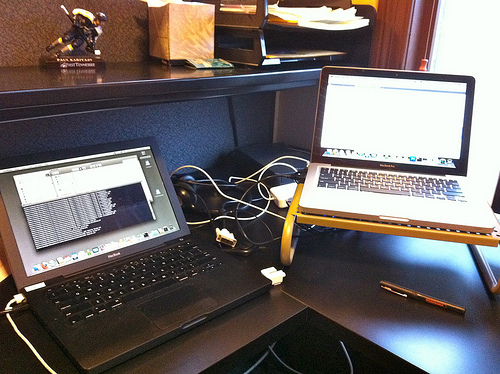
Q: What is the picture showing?
A: It is showing a station.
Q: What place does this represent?
A: It represents the station.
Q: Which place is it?
A: It is a station.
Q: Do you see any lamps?
A: No, there are no lamps.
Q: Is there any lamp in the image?
A: No, there are no lamps.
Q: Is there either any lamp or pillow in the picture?
A: No, there are no lamps or pillows.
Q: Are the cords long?
A: Yes, the cords are long.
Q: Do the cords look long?
A: Yes, the cords are long.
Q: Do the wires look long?
A: Yes, the wires are long.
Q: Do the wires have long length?
A: Yes, the wires are long.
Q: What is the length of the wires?
A: The wires are long.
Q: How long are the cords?
A: The cords are long.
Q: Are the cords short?
A: No, the cords are long.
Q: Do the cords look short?
A: No, the cords are long.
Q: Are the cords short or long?
A: The cords are long.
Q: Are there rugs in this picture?
A: No, there are no rugs.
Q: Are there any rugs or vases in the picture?
A: No, there are no rugs or vases.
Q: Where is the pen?
A: The pen is on the station.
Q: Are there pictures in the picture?
A: No, there are no pictures.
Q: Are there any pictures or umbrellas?
A: No, there are no pictures or umbrellas.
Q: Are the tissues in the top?
A: Yes, the tissues are in the top of the image.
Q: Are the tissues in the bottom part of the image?
A: No, the tissues are in the top of the image.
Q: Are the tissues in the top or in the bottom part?
A: The tissues are in the top of the image.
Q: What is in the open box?
A: The tissues are in the box.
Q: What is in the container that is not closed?
A: The tissues are in the box.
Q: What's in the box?
A: The tissues are in the box.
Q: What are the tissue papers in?
A: The tissue papers are in the box.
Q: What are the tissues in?
A: The tissue papers are in the box.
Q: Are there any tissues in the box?
A: Yes, there are tissues in the box.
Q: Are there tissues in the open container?
A: Yes, there are tissues in the box.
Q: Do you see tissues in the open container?
A: Yes, there are tissues in the box.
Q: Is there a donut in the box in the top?
A: No, there are tissues in the box.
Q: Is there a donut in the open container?
A: No, there are tissues in the box.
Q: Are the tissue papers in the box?
A: Yes, the tissue papers are in the box.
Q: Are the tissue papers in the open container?
A: Yes, the tissue papers are in the box.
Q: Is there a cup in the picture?
A: No, there are no cups.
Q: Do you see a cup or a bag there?
A: No, there are no cups or bags.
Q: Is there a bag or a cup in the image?
A: No, there are no cups or bags.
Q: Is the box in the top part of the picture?
A: Yes, the box is in the top of the image.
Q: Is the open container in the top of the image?
A: Yes, the box is in the top of the image.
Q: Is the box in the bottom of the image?
A: No, the box is in the top of the image.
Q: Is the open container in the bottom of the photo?
A: No, the box is in the top of the image.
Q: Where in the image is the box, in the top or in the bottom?
A: The box is in the top of the image.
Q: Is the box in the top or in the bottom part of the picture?
A: The box is in the top of the image.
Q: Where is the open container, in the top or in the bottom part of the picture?
A: The box is in the top of the image.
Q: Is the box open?
A: Yes, the box is open.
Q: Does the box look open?
A: Yes, the box is open.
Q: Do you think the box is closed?
A: No, the box is open.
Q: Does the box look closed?
A: No, the box is open.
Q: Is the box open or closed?
A: The box is open.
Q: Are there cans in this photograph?
A: No, there are no cans.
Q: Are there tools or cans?
A: No, there are no cans or tools.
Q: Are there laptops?
A: Yes, there is a laptop.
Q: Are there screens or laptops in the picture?
A: Yes, there is a laptop.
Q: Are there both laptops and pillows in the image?
A: No, there is a laptop but no pillows.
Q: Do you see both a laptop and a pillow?
A: No, there is a laptop but no pillows.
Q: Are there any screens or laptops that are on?
A: Yes, the laptop is on.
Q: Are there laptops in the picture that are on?
A: Yes, there is a laptop that is on.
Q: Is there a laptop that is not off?
A: Yes, there is a laptop that is on.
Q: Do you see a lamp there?
A: No, there are no lamps.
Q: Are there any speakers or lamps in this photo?
A: No, there are no lamps or speakers.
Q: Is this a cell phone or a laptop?
A: This is a laptop.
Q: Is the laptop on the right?
A: Yes, the laptop is on the right of the image.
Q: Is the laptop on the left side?
A: No, the laptop is on the right of the image.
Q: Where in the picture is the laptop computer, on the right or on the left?
A: The laptop computer is on the right of the image.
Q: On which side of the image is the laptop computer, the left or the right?
A: The laptop computer is on the right of the image.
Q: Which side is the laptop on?
A: The laptop is on the right of the image.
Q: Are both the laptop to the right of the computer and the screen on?
A: Yes, both the laptop and the screen are on.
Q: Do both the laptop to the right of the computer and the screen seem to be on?
A: Yes, both the laptop and the screen are on.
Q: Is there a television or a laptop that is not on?
A: No, there is a laptop but it is on.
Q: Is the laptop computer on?
A: Yes, the laptop computer is on.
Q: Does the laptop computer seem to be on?
A: Yes, the laptop computer is on.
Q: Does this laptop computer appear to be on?
A: Yes, the laptop computer is on.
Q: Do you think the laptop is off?
A: No, the laptop is on.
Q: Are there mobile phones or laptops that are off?
A: No, there is a laptop but it is on.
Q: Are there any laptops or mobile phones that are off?
A: No, there is a laptop but it is on.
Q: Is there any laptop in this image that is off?
A: No, there is a laptop but it is on.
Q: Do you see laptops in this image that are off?
A: No, there is a laptop but it is on.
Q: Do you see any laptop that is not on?
A: No, there is a laptop but it is on.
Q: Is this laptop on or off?
A: The laptop is on.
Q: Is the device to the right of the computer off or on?
A: The laptop is on.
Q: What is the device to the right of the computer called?
A: The device is a laptop.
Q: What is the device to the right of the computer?
A: The device is a laptop.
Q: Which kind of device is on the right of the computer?
A: The device is a laptop.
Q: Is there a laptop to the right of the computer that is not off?
A: Yes, there is a laptop to the right of the computer.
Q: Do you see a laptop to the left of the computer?
A: No, the laptop is to the right of the computer.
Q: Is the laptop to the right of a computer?
A: Yes, the laptop is to the right of a computer.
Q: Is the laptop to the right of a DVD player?
A: No, the laptop is to the right of a computer.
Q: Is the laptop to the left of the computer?
A: No, the laptop is to the right of the computer.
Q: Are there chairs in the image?
A: No, there are no chairs.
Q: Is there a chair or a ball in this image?
A: No, there are no chairs or balls.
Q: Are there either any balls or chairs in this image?
A: No, there are no chairs or balls.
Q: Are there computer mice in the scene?
A: Yes, there is a computer mouse.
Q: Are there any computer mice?
A: Yes, there is a computer mouse.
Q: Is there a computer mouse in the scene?
A: Yes, there is a computer mouse.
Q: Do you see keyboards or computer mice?
A: Yes, there is a computer mouse.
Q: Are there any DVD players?
A: No, there are no DVD players.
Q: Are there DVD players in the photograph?
A: No, there are no DVD players.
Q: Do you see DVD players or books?
A: No, there are no DVD players or books.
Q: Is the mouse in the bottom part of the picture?
A: Yes, the mouse is in the bottom of the image.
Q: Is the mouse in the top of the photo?
A: No, the mouse is in the bottom of the image.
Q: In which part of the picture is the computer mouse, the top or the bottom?
A: The computer mouse is in the bottom of the image.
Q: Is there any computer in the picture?
A: Yes, there is a computer.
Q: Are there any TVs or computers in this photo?
A: Yes, there is a computer.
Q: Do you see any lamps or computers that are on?
A: Yes, the computer is on.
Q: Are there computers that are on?
A: Yes, there is a computer that is on.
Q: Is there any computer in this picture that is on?
A: Yes, there is a computer that is on.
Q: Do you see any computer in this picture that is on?
A: Yes, there is a computer that is on.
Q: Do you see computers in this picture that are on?
A: Yes, there is a computer that is on.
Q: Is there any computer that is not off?
A: Yes, there is a computer that is on.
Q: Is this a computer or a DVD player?
A: This is a computer.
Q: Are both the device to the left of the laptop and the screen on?
A: Yes, both the computer and the screen are on.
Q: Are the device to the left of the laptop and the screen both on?
A: Yes, both the computer and the screen are on.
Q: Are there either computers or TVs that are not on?
A: No, there is a computer but it is on.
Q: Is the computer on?
A: Yes, the computer is on.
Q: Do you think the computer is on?
A: Yes, the computer is on.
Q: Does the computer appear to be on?
A: Yes, the computer is on.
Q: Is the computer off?
A: No, the computer is on.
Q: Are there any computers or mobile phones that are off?
A: No, there is a computer but it is on.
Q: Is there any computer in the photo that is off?
A: No, there is a computer but it is on.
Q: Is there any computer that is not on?
A: No, there is a computer but it is on.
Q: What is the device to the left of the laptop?
A: The device is a computer.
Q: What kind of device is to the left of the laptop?
A: The device is a computer.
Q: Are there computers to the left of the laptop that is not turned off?
A: Yes, there is a computer to the left of the laptop.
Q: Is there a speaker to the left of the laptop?
A: No, there is a computer to the left of the laptop.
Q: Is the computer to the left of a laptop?
A: Yes, the computer is to the left of a laptop.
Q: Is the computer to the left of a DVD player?
A: No, the computer is to the left of a laptop.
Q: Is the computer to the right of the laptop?
A: No, the computer is to the left of the laptop.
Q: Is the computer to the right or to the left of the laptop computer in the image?
A: The computer is to the left of the laptop computer.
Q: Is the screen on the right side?
A: Yes, the screen is on the right of the image.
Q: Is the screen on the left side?
A: No, the screen is on the right of the image.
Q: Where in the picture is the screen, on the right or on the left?
A: The screen is on the right of the image.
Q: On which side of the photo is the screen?
A: The screen is on the right of the image.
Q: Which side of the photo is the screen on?
A: The screen is on the right of the image.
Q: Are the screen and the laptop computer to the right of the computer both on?
A: Yes, both the screen and the laptop are on.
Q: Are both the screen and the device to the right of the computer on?
A: Yes, both the screen and the laptop are on.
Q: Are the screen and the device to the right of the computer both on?
A: Yes, both the screen and the laptop are on.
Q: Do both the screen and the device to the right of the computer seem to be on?
A: Yes, both the screen and the laptop are on.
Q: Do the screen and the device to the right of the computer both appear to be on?
A: Yes, both the screen and the laptop are on.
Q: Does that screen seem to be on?
A: Yes, the screen is on.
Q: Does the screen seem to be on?
A: Yes, the screen is on.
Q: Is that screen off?
A: No, the screen is on.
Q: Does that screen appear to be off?
A: No, the screen is on.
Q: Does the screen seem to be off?
A: No, the screen is on.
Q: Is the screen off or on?
A: The screen is on.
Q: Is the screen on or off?
A: The screen is on.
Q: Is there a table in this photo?
A: Yes, there is a table.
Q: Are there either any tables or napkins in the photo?
A: Yes, there is a table.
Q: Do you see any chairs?
A: No, there are no chairs.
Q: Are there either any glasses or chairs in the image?
A: No, there are no chairs or glasses.